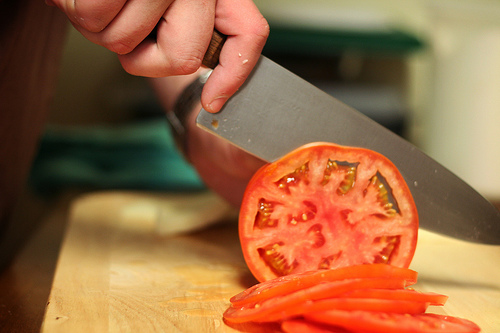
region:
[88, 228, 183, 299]
this is a board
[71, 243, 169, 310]
the board is wooden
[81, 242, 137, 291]
the board is brown in color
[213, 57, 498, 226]
this is a knife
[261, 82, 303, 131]
the knife is metallic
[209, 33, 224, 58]
this is a handle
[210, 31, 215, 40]
the handle is brown in color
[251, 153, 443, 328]
these are tomato slices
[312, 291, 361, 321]
the slices are red in color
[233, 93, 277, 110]
the knife is shiny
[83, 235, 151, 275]
this is a chopboard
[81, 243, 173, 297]
the chopboard is wooden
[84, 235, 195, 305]
the board is brown in color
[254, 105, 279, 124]
the knife is metallic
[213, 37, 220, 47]
this is a handle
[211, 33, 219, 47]
the handle is wooden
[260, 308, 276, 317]
the tomato is red in color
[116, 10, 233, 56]
these are some fingers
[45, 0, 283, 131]
four light-colored fingers grasping a knife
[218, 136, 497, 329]
large red tomato being sliced by a knife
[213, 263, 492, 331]
red tomato slices stacked on a wooden cutting board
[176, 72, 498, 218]
metal chef's knife slicing a tomato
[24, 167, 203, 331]
light-colored wooden cutting board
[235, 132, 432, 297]
round red tomato with seeds showing from a cut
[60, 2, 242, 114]
four fingers curled around the handle of a knife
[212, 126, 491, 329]
a large tomato being cut into slices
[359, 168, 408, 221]
tomato seeds showing in red tomato flesh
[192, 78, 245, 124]
a finger, with rough fingernail, on a metal background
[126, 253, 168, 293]
this is a board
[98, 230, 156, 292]
the board is wooden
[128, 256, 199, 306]
the board is brown in color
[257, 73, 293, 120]
this is a knife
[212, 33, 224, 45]
this is the handle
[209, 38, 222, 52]
the handle is wooden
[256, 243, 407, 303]
these are tomato slices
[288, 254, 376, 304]
the slices are red in color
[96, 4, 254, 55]
these are the fingers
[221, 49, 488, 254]
Large silver blade on knife.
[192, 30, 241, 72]
Wood handle on knife.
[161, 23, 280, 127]
Person holding knife.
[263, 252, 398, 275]
Thin slice of tomato.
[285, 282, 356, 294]
Thin sliced tomato on counter.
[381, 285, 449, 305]
Thin slice of tomato.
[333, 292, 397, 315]
Thin slice of tomato.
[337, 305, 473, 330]
Thin red slice of tomato.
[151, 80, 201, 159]
Person wearing black band on wrist.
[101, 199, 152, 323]
Light brown wood cutting board.